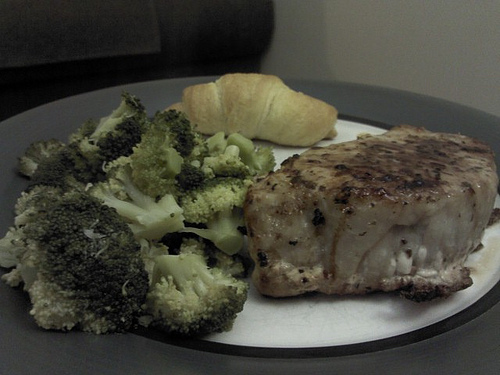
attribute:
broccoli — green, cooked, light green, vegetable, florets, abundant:
[15, 123, 235, 320]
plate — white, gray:
[25, 114, 79, 138]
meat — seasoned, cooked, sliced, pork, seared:
[269, 143, 456, 269]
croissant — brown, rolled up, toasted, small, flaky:
[189, 89, 321, 145]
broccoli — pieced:
[28, 138, 93, 182]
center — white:
[274, 310, 342, 335]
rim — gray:
[355, 91, 417, 115]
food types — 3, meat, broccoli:
[65, 111, 356, 249]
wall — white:
[354, 43, 415, 59]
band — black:
[282, 343, 344, 362]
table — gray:
[200, 51, 238, 59]